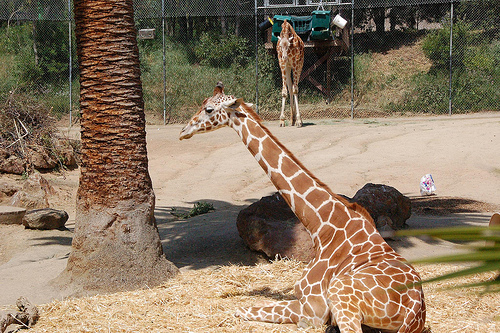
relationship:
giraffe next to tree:
[176, 78, 433, 326] [70, 2, 180, 306]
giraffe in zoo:
[176, 78, 433, 326] [5, 4, 499, 329]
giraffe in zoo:
[273, 18, 312, 129] [5, 4, 499, 329]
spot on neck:
[260, 134, 283, 174] [233, 108, 357, 240]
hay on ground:
[30, 253, 496, 331] [13, 110, 497, 318]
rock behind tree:
[18, 208, 69, 234] [70, 2, 180, 306]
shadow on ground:
[39, 183, 494, 305] [13, 110, 497, 318]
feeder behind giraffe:
[271, 11, 336, 46] [273, 18, 312, 129]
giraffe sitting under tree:
[176, 78, 433, 326] [70, 2, 180, 306]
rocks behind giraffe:
[239, 172, 411, 268] [176, 78, 433, 326]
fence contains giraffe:
[2, 1, 500, 127] [176, 78, 433, 326]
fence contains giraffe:
[2, 1, 500, 127] [273, 18, 312, 129]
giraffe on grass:
[176, 78, 433, 326] [43, 212, 500, 323]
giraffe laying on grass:
[176, 78, 433, 326] [43, 212, 500, 323]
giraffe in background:
[273, 18, 312, 129] [6, 7, 499, 231]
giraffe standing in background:
[273, 18, 312, 129] [6, 7, 499, 231]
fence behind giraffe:
[2, 1, 500, 127] [273, 18, 312, 129]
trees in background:
[7, 17, 500, 134] [6, 7, 499, 231]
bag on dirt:
[422, 177, 438, 196] [8, 105, 488, 266]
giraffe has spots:
[176, 78, 433, 326] [232, 116, 411, 316]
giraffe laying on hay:
[176, 78, 433, 326] [30, 253, 496, 331]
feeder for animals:
[257, 13, 336, 52] [174, 18, 432, 328]